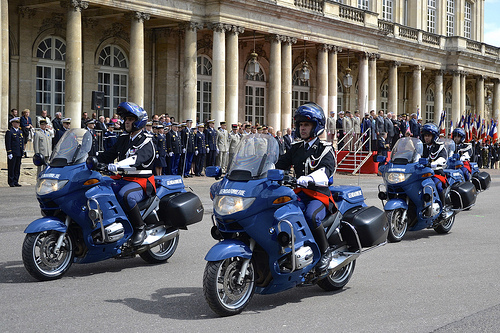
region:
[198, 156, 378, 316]
a blue motorcycle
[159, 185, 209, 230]
a black saddlebag on a motorcycle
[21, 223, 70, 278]
the black wheel of a motorcycle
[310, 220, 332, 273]
a black boot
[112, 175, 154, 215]
blue pants with a black stripe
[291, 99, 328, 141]
a blue helmet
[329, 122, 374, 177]
metal stairs off a red platform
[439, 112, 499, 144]
blue, white, and red flags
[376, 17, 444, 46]
a parapet railing on a rooftop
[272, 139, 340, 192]
a uniform jacket on a motorcycle rider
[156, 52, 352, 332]
the bikes are blue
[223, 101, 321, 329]
the bikes are blue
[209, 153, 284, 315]
the bikes are blue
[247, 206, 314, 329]
the bikes are blue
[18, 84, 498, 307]
Several Uniformed officers on motor bikes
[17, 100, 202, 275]
Man on blue motor bike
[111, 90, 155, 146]
Man Wearing blue safety Helmet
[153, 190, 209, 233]
Black Equipment Case on a motorbike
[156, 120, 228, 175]
Groups of uniformed military or policemen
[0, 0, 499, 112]
Fairly old ornate building in the background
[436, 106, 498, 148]
Various hanging flags on poles in the background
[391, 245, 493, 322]
Grey patches of cement road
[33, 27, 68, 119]
Large Glass Windows on the building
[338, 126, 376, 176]
A small set of Solid metal Stairs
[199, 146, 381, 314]
motorcycle is blue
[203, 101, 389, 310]
Rider on blue motorcycle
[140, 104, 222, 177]
People in front of building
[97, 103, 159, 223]
Motorcycle rider in red and blue uniform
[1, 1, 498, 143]
Older building in background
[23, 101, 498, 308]
Riders in motorcycle parade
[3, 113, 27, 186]
Man in dress uniform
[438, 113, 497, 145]
red, white, and blue flags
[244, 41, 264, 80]
Large light globes hanging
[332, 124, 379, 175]
Steps leading to stage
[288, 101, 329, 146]
blue helmets on riders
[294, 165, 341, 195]
white gloves on riders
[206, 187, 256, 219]
head lights on front of bike on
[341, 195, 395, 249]
storage area mounted to motorcycle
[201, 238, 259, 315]
small tires on motorcycle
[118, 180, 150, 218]
blue pants with black stripes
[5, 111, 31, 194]
men in formal uniforms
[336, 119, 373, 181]
white stairway with hand rails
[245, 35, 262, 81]
lanterns hanging from building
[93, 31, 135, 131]
windows with lots of panes